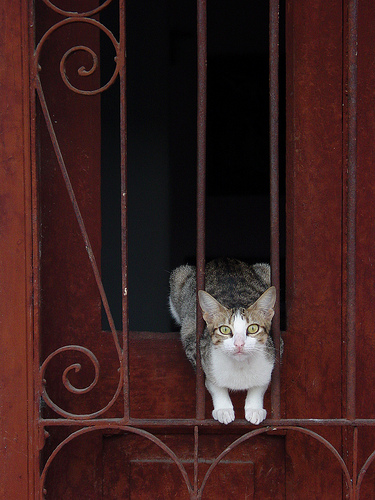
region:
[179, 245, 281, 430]
a curious cat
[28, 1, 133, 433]
a metal door pattern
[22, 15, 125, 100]
an spiral metal form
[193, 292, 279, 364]
the head of the cat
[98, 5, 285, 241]
the dark interior of the house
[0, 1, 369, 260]
the red door of the house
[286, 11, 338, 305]
varnished wood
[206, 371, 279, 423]
two white legs of the cat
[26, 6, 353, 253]
varnished metal structure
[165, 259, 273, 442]
the cat paying attention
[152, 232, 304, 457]
A cat hanging out a door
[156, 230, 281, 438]
A calico cat on a door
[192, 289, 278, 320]
Cat ears pointed up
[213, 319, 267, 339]
Yellow cat eyes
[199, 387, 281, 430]
Cat paws on a door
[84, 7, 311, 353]
A door missing a panel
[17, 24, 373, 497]
An iron door with a cat on it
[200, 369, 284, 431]
A cat with white paws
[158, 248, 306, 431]
A cat coming out of a door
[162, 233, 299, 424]
A cat has its paws on a metal door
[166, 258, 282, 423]
the cat staring at the camera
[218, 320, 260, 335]
the cat's two eyes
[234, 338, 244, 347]
the cat's pink nose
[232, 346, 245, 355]
the cat's mouth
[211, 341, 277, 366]
the whiskers on the cat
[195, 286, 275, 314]
the cat's two ears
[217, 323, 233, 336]
the cat's right eye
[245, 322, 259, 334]
the cat's left eye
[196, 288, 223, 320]
the cat's right ear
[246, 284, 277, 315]
the cat's left ear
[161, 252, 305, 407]
A gray and white cat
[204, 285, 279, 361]
a cats head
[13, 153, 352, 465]
a wooden door with metal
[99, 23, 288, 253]
A open window in the door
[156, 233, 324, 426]
A cat looking out a door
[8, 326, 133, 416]
metal swirl on a door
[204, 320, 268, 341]
Yellow eyes of a cat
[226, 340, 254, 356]
Pink nose of a cat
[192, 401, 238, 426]
Right paw of a cat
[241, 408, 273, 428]
left paw of a cat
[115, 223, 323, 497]
cat is gray and white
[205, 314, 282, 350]
cat's eyes are yellow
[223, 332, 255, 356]
cat's nose is pink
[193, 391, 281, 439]
cat's paws on rail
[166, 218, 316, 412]
cat laying through opening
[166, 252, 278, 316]
cat's ears pointing upwards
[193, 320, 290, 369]
cat's whiskers are white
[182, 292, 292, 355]
cat is looking at camera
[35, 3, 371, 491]
the object is brown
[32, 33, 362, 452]
the railings are brown